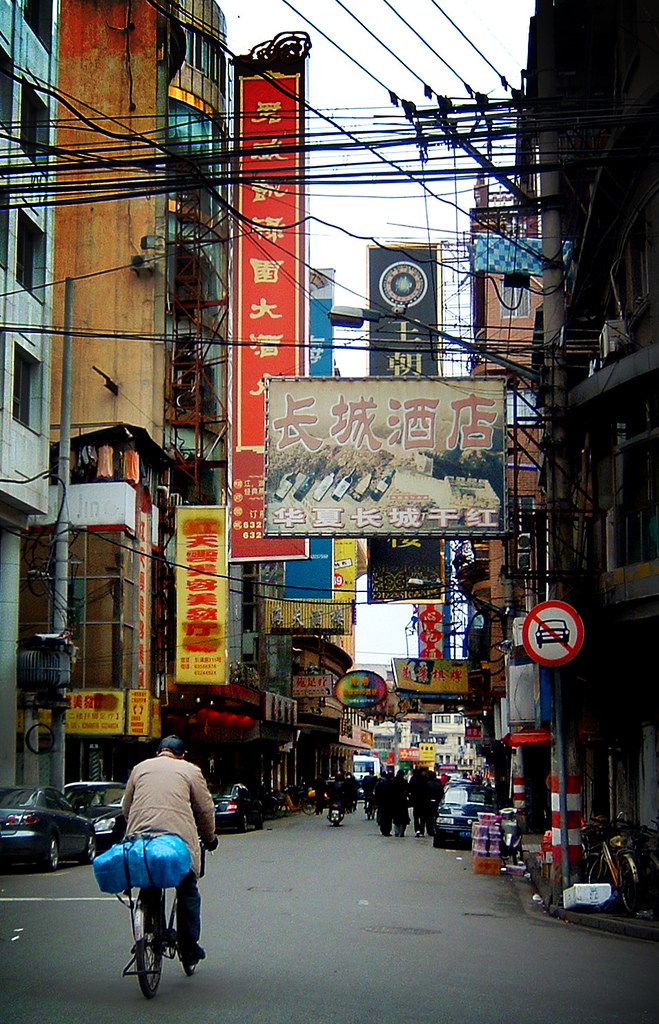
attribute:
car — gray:
[1, 772, 96, 881]